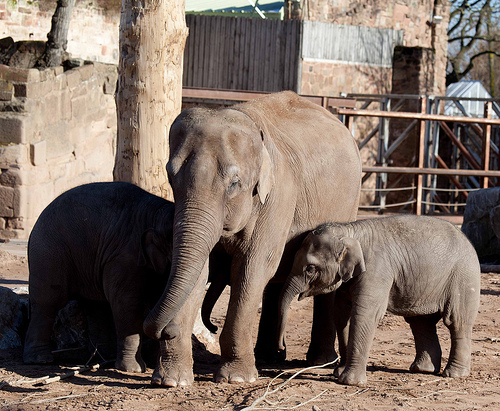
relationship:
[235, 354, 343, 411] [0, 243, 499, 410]
limb on ground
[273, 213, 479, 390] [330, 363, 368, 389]
elephant has feet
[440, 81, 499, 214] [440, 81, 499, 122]
building has roof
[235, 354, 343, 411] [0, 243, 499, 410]
branch on ground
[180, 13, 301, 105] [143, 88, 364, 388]
fence behind elephant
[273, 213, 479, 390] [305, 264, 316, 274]
elephant has eye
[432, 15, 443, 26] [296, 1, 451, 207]
light on building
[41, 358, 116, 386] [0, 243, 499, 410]
branch on ground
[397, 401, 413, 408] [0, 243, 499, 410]
stones on ground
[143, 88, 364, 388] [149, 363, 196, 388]
elephant has foot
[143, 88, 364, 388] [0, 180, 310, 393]
elephant has shadow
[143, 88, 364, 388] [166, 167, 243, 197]
elephant has eyes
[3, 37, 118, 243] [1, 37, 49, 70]
wall" has stones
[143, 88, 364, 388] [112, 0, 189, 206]
elephant under tree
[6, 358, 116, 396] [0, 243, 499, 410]
branch on ground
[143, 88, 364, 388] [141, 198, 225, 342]
elephant has trunk